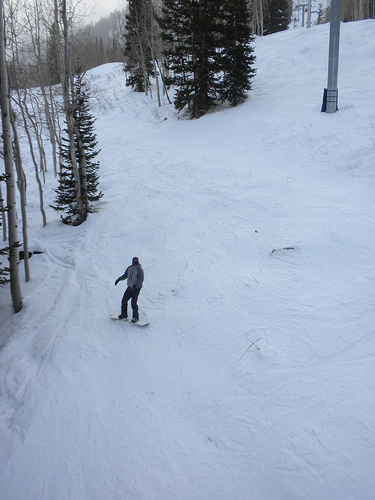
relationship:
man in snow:
[108, 252, 155, 332] [3, 88, 374, 499]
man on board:
[108, 252, 155, 332] [108, 309, 150, 330]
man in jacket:
[108, 252, 155, 332] [123, 265, 143, 291]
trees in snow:
[0, 1, 268, 274] [3, 88, 374, 499]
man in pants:
[108, 252, 155, 332] [117, 285, 144, 316]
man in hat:
[108, 252, 155, 332] [132, 258, 140, 263]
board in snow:
[108, 309, 150, 330] [3, 88, 374, 499]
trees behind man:
[0, 1, 268, 274] [108, 252, 155, 332]